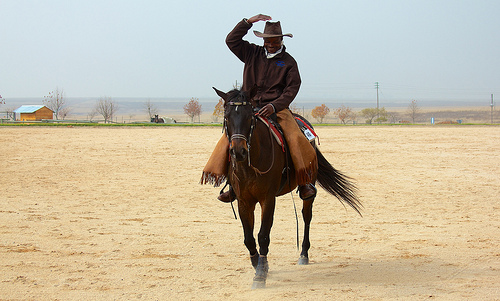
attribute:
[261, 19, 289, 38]
hat — brown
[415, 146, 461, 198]
sand — dry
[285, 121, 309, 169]
chaps — leather, tan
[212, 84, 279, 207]
horse — brown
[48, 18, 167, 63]
sky — overcast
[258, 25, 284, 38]
cowboy hat — brown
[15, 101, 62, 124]
building — yellow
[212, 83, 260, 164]
horse head — brown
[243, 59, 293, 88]
jacket — brown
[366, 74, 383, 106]
powerline — tall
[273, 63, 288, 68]
writing — blue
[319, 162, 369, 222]
tail — waving, brown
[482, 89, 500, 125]
telephone pole — gray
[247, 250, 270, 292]
hoofs — dirty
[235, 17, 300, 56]
cowboy — black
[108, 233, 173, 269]
terrain — sandy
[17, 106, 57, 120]
house — yellow, small, wooden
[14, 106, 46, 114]
roof — yellow, white